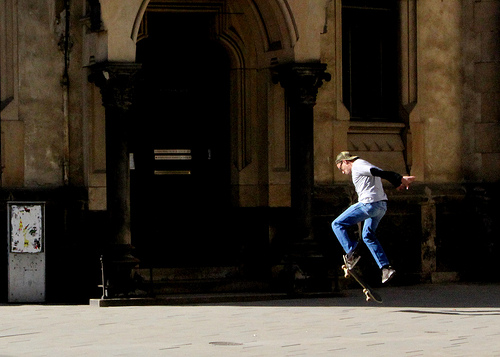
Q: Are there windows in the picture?
A: Yes, there is a window.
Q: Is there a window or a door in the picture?
A: Yes, there is a window.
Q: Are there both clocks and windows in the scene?
A: No, there is a window but no clocks.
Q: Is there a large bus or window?
A: Yes, there is a large window.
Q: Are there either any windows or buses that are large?
A: Yes, the window is large.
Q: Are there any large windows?
A: Yes, there is a large window.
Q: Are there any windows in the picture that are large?
A: Yes, there is a window that is large.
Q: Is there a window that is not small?
A: Yes, there is a large window.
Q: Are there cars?
A: No, there are no cars.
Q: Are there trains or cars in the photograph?
A: No, there are no cars or trains.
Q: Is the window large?
A: Yes, the window is large.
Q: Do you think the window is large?
A: Yes, the window is large.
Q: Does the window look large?
A: Yes, the window is large.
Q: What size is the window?
A: The window is large.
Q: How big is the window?
A: The window is large.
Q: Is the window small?
A: No, the window is large.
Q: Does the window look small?
A: No, the window is large.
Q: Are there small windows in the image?
A: No, there is a window but it is large.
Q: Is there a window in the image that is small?
A: No, there is a window but it is large.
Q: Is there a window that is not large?
A: No, there is a window but it is large.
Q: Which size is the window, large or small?
A: The window is large.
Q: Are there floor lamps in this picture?
A: No, there are no floor lamps.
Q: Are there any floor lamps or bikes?
A: No, there are no floor lamps or bikes.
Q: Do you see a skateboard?
A: Yes, there is a skateboard.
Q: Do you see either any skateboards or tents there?
A: Yes, there is a skateboard.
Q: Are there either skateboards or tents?
A: Yes, there is a skateboard.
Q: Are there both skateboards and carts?
A: No, there is a skateboard but no carts.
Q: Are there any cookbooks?
A: No, there are no cookbooks.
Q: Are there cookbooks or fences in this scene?
A: No, there are no cookbooks or fences.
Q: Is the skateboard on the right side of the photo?
A: Yes, the skateboard is on the right of the image.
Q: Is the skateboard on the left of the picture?
A: No, the skateboard is on the right of the image.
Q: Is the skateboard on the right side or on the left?
A: The skateboard is on the right of the image.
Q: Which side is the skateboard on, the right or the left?
A: The skateboard is on the right of the image.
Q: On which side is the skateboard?
A: The skateboard is on the right of the image.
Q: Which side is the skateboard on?
A: The skateboard is on the right of the image.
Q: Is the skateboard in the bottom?
A: Yes, the skateboard is in the bottom of the image.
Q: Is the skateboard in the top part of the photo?
A: No, the skateboard is in the bottom of the image.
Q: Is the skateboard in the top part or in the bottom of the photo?
A: The skateboard is in the bottom of the image.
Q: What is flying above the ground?
A: The skateboard is flying above the ground.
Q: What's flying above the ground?
A: The skateboard is flying above the ground.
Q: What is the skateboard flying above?
A: The skateboard is flying above the ground.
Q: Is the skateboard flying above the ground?
A: Yes, the skateboard is flying above the ground.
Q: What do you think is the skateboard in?
A: The skateboard is in the air.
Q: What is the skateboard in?
A: The skateboard is in the air.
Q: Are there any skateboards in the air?
A: Yes, there is a skateboard in the air.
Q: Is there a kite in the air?
A: No, there is a skateboard in the air.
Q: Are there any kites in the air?
A: No, there is a skateboard in the air.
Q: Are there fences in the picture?
A: No, there are no fences.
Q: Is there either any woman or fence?
A: No, there are no fences or women.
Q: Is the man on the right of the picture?
A: Yes, the man is on the right of the image.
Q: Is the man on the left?
A: No, the man is on the right of the image.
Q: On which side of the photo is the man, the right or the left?
A: The man is on the right of the image.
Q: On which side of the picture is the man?
A: The man is on the right of the image.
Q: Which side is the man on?
A: The man is on the right of the image.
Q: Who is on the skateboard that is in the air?
A: The man is on the skateboard.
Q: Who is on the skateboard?
A: The man is on the skateboard.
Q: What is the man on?
A: The man is on the skateboard.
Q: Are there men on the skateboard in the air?
A: Yes, there is a man on the skateboard.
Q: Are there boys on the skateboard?
A: No, there is a man on the skateboard.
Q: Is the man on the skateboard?
A: Yes, the man is on the skateboard.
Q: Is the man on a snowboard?
A: No, the man is on the skateboard.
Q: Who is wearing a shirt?
A: The man is wearing a shirt.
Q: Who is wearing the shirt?
A: The man is wearing a shirt.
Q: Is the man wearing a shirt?
A: Yes, the man is wearing a shirt.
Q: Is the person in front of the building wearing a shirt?
A: Yes, the man is wearing a shirt.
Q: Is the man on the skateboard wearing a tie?
A: No, the man is wearing a shirt.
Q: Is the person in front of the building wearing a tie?
A: No, the man is wearing a shirt.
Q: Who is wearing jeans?
A: The man is wearing jeans.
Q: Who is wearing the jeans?
A: The man is wearing jeans.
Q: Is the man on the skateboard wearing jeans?
A: Yes, the man is wearing jeans.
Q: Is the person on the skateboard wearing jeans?
A: Yes, the man is wearing jeans.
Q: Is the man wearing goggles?
A: No, the man is wearing jeans.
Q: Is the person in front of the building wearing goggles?
A: No, the man is wearing jeans.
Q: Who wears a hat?
A: The man wears a hat.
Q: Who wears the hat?
A: The man wears a hat.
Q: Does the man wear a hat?
A: Yes, the man wears a hat.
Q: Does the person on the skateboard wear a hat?
A: Yes, the man wears a hat.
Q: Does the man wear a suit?
A: No, the man wears a hat.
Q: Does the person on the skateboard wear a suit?
A: No, the man wears a hat.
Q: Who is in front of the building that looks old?
A: The man is in front of the building.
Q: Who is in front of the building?
A: The man is in front of the building.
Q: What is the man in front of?
A: The man is in front of the building.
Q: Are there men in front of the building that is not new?
A: Yes, there is a man in front of the building.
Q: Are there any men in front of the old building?
A: Yes, there is a man in front of the building.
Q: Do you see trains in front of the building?
A: No, there is a man in front of the building.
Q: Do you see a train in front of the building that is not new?
A: No, there is a man in front of the building.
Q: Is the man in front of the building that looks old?
A: Yes, the man is in front of the building.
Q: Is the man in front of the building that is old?
A: Yes, the man is in front of the building.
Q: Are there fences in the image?
A: No, there are no fences.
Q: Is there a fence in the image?
A: No, there are no fences.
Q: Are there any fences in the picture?
A: No, there are no fences.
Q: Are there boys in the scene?
A: No, there are no boys.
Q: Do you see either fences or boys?
A: No, there are no boys or fences.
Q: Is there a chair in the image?
A: No, there are no chairs.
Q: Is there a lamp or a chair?
A: No, there are no chairs or lamps.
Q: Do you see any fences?
A: No, there are no fences.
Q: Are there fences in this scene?
A: No, there are no fences.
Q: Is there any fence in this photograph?
A: No, there are no fences.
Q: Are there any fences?
A: No, there are no fences.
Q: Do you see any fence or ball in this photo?
A: No, there are no fences or balls.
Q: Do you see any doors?
A: Yes, there is a door.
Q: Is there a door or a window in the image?
A: Yes, there is a door.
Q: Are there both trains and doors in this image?
A: No, there is a door but no trains.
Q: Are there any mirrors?
A: No, there are no mirrors.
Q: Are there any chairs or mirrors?
A: No, there are no mirrors or chairs.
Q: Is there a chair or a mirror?
A: No, there are no mirrors or chairs.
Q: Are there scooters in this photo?
A: No, there are no scooters.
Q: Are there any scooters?
A: No, there are no scooters.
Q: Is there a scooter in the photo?
A: No, there are no scooters.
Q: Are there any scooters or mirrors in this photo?
A: No, there are no scooters or mirrors.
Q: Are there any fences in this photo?
A: No, there are no fences.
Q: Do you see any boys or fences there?
A: No, there are no fences or boys.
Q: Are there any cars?
A: No, there are no cars.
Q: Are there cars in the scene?
A: No, there are no cars.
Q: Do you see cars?
A: No, there are no cars.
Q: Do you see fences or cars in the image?
A: No, there are no cars or fences.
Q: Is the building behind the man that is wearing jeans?
A: Yes, the building is behind the man.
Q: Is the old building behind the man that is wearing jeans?
A: Yes, the building is behind the man.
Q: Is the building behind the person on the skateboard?
A: Yes, the building is behind the man.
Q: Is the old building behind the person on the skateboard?
A: Yes, the building is behind the man.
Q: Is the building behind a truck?
A: No, the building is behind the man.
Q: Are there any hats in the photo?
A: Yes, there is a hat.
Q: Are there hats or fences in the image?
A: Yes, there is a hat.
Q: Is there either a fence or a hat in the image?
A: Yes, there is a hat.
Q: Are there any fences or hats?
A: Yes, there is a hat.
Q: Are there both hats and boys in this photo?
A: No, there is a hat but no boys.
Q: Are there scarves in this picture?
A: No, there are no scarves.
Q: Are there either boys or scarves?
A: No, there are no scarves or boys.